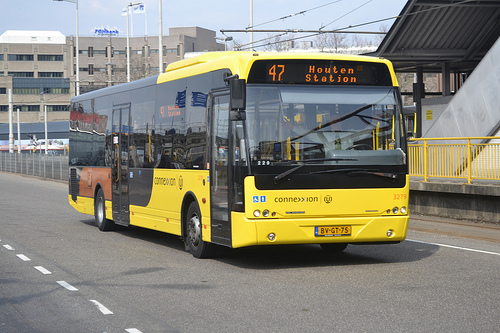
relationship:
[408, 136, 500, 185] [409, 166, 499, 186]
fence on walkway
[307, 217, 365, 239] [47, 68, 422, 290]
license plate in bus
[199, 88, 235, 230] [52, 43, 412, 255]
door of bus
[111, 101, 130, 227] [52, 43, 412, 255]
back door of bus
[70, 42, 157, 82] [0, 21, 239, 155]
windows on building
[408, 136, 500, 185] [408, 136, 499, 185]
fence of fence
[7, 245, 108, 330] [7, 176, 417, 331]
lines on street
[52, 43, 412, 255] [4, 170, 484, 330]
bus on street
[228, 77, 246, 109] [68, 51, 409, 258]
mirror on bus